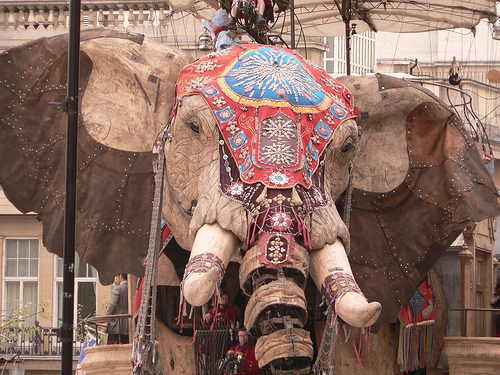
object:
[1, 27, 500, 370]
elephant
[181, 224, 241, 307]
tusk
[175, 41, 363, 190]
fabric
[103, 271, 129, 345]
man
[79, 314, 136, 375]
balcony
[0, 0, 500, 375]
building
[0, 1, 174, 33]
balcony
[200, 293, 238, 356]
man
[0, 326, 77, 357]
balcony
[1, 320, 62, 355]
railing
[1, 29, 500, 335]
head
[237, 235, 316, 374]
trunk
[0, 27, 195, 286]
ear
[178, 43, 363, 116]
forehead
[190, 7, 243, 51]
man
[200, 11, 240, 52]
gown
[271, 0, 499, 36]
sail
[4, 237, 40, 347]
window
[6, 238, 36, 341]
curtains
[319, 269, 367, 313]
decoration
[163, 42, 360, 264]
hat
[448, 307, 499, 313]
railing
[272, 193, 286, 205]
diamond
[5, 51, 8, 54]
dot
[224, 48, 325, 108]
circle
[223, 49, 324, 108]
design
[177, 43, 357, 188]
cloth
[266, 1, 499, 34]
awning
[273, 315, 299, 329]
part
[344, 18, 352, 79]
pole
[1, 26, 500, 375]
statue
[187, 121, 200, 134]
right eye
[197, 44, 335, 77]
back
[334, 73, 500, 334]
left ear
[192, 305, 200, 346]
ribbon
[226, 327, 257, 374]
man